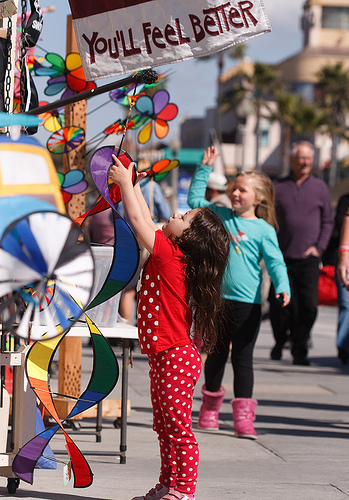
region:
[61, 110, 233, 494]
child reaching for colorful wind spinners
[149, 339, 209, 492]
child is wearing red pants with white dots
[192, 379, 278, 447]
child wearing pink boots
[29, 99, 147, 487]
display of colorful wind spinners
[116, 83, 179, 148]
spinning flowers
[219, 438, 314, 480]
pavement is grey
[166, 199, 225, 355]
girl reaching has long brown hair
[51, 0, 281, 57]
sign above the display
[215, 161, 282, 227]
blond girl looking at display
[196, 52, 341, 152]
blurry palm trees in the background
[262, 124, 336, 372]
a man walking with his hands in his pocket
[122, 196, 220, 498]
young girl wearing red with white polka dots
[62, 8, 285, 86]
bottom of flag that states you feel better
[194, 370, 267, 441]
pair of pink moon boots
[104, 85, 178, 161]
rainbow colored pin wheel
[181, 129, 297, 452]
young blonde girl wearing long sleeve shirt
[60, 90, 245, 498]
a young girl reaching for a pinwheel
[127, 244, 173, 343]
minnie mouse on the front of the girls shirt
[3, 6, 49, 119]
black chains hanging from building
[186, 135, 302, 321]
girl with her right hand in the air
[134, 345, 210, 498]
red polka dot pants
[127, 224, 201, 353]
red polka dot shirt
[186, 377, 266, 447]
a pair of pink boots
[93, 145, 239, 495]
a girl with brown hair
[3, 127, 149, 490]
colorful wind socks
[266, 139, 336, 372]
a man in a purple shirt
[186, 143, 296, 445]
a young blonde girl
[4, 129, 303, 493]
children looking at colorful decorations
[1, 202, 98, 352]
a blue and white pinwheel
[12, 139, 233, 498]
girl reaching for a decoration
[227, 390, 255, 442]
a pink boot on the girl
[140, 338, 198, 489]
a red and white pair of pants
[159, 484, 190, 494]
a pink and white shoe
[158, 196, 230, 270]
the head of the girl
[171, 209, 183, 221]
the nose of the girl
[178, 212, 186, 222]
the eye of the girl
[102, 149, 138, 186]
the hand of the girl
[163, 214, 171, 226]
the mouth of the girl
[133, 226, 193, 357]
a red and white tee shirt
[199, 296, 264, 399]
a black pair of pants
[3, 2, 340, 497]
people at a street fair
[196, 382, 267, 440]
pink boots on a little girl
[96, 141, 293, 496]
little girls near outdoor decorations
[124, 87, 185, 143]
flower decoration for outside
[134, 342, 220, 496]
red polka dot pants of a little girl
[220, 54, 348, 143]
palm trees in the background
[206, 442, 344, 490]
concrete street where people are walking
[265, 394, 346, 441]
shadows casted on the ground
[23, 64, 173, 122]
black pole holding flag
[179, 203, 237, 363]
long brown hair of a little girl